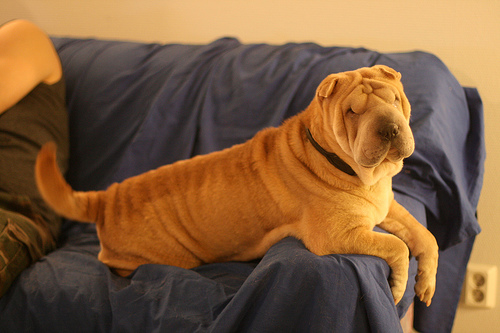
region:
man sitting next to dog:
[0, 19, 75, 330]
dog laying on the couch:
[25, 72, 439, 306]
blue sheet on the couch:
[13, 21, 474, 330]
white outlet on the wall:
[466, 263, 496, 305]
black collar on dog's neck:
[303, 126, 365, 175]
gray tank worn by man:
[2, 71, 66, 211]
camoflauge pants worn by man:
[2, 194, 59, 302]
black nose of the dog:
[380, 124, 396, 136]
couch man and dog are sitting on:
[2, 17, 467, 332]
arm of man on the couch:
[0, 11, 64, 108]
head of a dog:
[308, 55, 425, 176]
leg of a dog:
[405, 229, 466, 309]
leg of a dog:
[324, 231, 395, 293]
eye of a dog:
[340, 92, 368, 127]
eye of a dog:
[385, 86, 409, 107]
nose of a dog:
[372, 121, 394, 139]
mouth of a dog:
[370, 142, 420, 169]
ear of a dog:
[312, 73, 342, 118]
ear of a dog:
[364, 63, 416, 98]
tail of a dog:
[28, 158, 85, 220]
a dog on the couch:
[93, 57, 490, 254]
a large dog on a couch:
[79, 61, 430, 321]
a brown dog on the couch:
[107, 32, 458, 332]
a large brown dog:
[77, 47, 446, 325]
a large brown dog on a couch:
[79, 33, 451, 262]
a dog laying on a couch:
[43, 66, 499, 303]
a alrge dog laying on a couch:
[103, 36, 438, 315]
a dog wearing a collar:
[78, 68, 474, 318]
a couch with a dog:
[124, 13, 434, 329]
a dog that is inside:
[94, 48, 378, 312]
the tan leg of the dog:
[294, 196, 406, 302]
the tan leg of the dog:
[380, 196, 439, 303]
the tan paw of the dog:
[389, 261, 408, 303]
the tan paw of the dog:
[418, 252, 438, 300]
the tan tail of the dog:
[32, 141, 97, 225]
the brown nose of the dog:
[380, 123, 397, 138]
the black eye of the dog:
[345, 104, 357, 116]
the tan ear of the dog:
[318, 75, 339, 97]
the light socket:
[466, 263, 493, 308]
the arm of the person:
[1, 20, 63, 113]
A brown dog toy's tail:
[26, 135, 103, 237]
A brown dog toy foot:
[358, 226, 414, 298]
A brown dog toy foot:
[392, 208, 449, 292]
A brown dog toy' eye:
[342, 92, 364, 121]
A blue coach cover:
[147, 60, 275, 122]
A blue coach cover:
[168, 280, 304, 332]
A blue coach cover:
[32, 267, 155, 332]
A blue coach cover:
[415, 58, 470, 188]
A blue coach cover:
[437, 203, 463, 325]